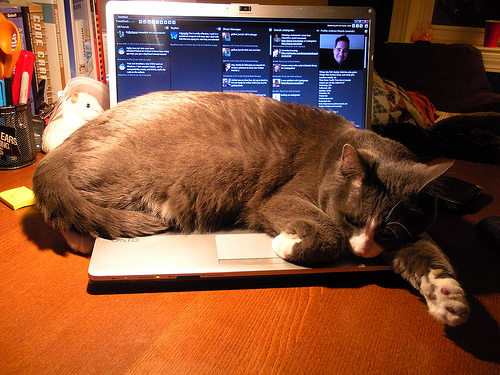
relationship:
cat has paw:
[33, 89, 468, 327] [390, 232, 469, 326]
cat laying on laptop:
[33, 89, 468, 327] [88, 0, 395, 284]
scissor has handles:
[0, 14, 23, 107] [0, 12, 23, 78]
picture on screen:
[318, 33, 367, 71] [114, 13, 369, 129]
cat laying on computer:
[33, 89, 468, 327] [88, 0, 395, 284]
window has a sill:
[387, 3, 499, 72] [472, 44, 499, 75]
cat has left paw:
[33, 89, 468, 327] [390, 232, 469, 326]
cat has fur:
[33, 89, 468, 327] [33, 92, 471, 328]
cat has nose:
[33, 89, 468, 327] [349, 237, 382, 257]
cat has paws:
[33, 89, 468, 327] [269, 227, 357, 268]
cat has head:
[33, 89, 468, 327] [318, 143, 457, 262]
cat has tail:
[33, 89, 468, 327] [33, 151, 173, 240]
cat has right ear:
[33, 89, 468, 327] [337, 143, 374, 190]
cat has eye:
[33, 89, 468, 327] [340, 210, 369, 230]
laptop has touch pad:
[88, 0, 395, 284] [214, 233, 278, 260]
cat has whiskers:
[33, 89, 468, 327] [380, 198, 412, 241]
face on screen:
[334, 37, 350, 64] [114, 13, 369, 129]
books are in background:
[0, 0, 108, 103] [0, 0, 499, 169]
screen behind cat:
[114, 13, 369, 129] [33, 89, 468, 327]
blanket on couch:
[371, 68, 441, 130] [371, 43, 500, 154]